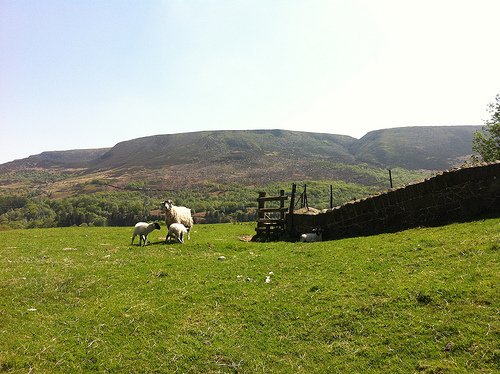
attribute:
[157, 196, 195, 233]
sheep — white, big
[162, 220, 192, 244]
sheep — baby, laying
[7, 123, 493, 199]
mountains — distant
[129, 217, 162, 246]
sheep — baby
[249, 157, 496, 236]
wall — stone, long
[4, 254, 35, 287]
plant — white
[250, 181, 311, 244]
fence — wooden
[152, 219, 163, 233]
face — black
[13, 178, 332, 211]
pasture — large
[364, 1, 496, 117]
sky — white, cloudy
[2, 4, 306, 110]
sky — blue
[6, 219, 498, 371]
field — green